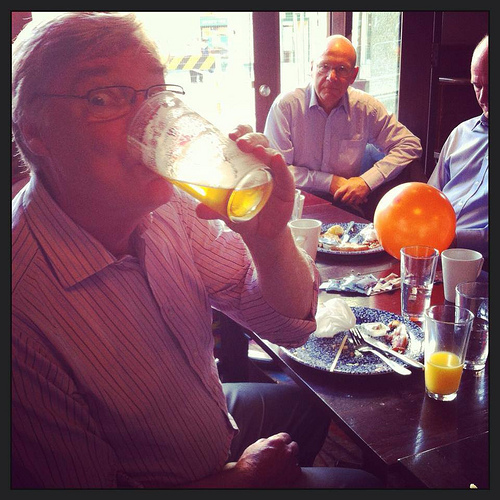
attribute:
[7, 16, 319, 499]
man — drinking, close, bald, white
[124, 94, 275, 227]
glass — clear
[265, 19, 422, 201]
person — looking, old, sitting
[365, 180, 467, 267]
ball — round, orange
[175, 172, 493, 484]
table — brown, long